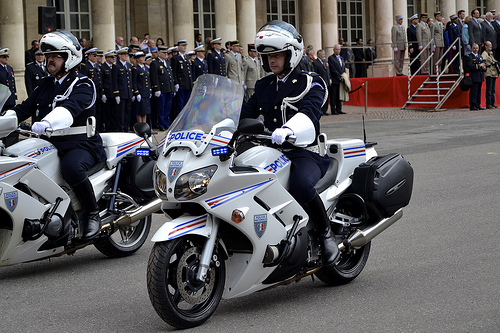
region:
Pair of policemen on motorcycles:
[1, 18, 415, 330]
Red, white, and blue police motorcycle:
[145, 71, 415, 328]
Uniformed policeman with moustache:
[15, 27, 107, 241]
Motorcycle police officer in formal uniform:
[241, 18, 344, 268]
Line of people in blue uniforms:
[0, 36, 227, 131]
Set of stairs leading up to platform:
[401, 36, 465, 112]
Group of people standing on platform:
[390, 8, 498, 77]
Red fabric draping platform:
[341, 71, 498, 109]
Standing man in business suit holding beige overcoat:
[327, 43, 352, 115]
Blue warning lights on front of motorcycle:
[133, 145, 234, 160]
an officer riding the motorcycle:
[142, 22, 405, 317]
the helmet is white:
[241, 8, 324, 95]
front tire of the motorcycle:
[155, 264, 204, 316]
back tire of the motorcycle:
[347, 259, 364, 276]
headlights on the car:
[182, 173, 204, 193]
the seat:
[320, 160, 337, 181]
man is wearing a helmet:
[260, 25, 298, 47]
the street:
[431, 198, 495, 282]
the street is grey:
[418, 231, 480, 303]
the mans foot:
[317, 234, 344, 261]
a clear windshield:
[185, 87, 229, 124]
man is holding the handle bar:
[269, 128, 287, 146]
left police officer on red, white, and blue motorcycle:
[0, 33, 162, 267]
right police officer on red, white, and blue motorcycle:
[133, 20, 415, 329]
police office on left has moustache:
[44, 60, 58, 67]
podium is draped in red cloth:
[325, 70, 497, 110]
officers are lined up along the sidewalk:
[1, 31, 352, 133]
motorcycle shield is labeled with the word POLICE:
[165, 128, 202, 142]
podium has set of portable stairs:
[400, 37, 468, 113]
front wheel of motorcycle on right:
[144, 233, 228, 329]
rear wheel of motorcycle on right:
[313, 214, 373, 285]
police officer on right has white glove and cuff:
[267, 110, 318, 147]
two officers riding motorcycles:
[0, 7, 415, 315]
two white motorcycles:
[0, 85, 419, 327]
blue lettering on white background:
[166, 128, 204, 145]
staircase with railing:
[398, 43, 468, 110]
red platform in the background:
[347, 71, 494, 109]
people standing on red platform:
[388, 9, 494, 64]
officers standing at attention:
[23, 34, 267, 100]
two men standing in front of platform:
[462, 38, 498, 108]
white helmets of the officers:
[34, 28, 305, 75]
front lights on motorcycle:
[145, 164, 214, 194]